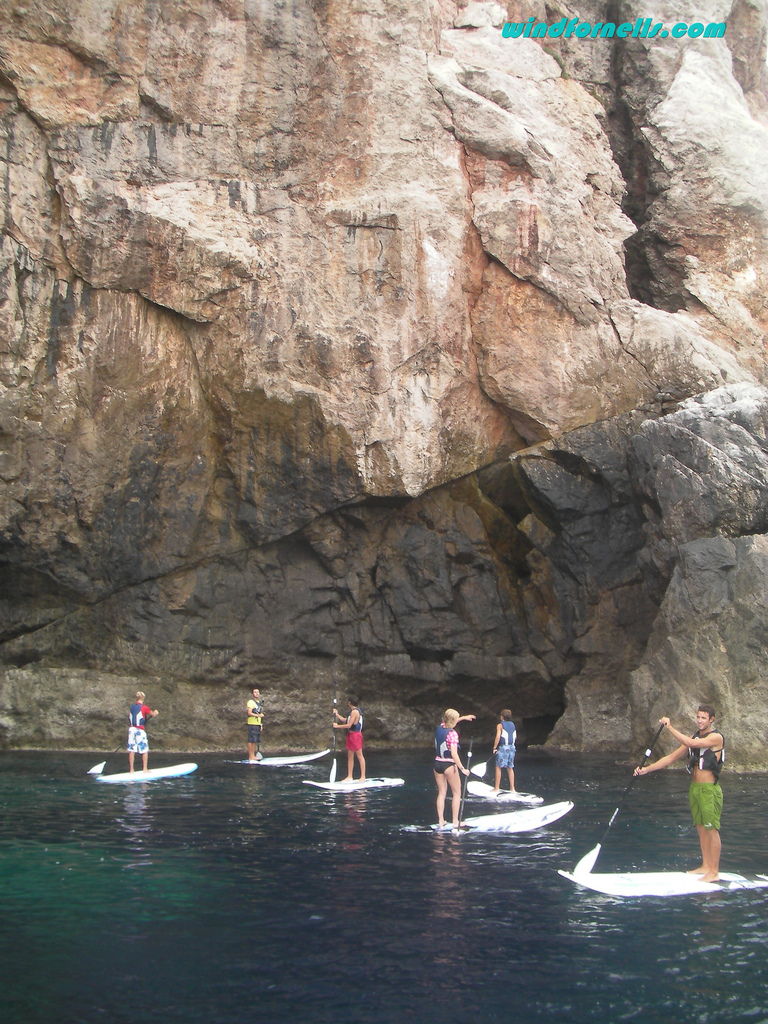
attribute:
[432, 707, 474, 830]
person — white, standing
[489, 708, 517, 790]
person — standing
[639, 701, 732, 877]
person — standing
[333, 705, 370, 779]
person — standing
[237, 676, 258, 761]
person — standing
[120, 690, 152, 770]
person — standing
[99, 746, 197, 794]
surfboard — white, long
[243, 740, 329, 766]
surfboard — white, long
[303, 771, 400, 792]
surfboard — white, long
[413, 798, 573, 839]
surfboard — white, long